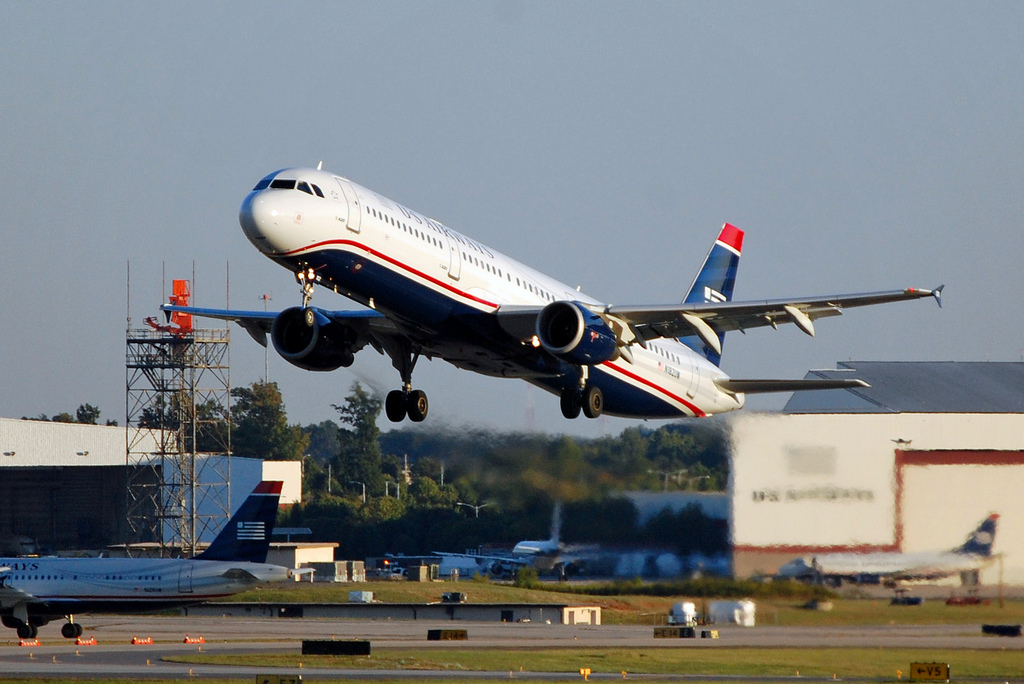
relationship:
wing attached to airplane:
[496, 284, 948, 365] [161, 159, 949, 423]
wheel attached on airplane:
[384, 390, 436, 423] [237, 167, 879, 453]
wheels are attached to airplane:
[557, 381, 605, 418] [161, 159, 949, 423]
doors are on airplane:
[332, 178, 367, 231] [161, 159, 949, 423]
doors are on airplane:
[438, 223, 471, 288] [161, 159, 949, 423]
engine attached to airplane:
[534, 297, 622, 368] [161, 159, 949, 423]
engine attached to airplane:
[269, 304, 360, 371] [161, 159, 949, 423]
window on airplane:
[267, 174, 300, 196] [161, 159, 949, 423]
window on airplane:
[297, 174, 311, 196] [161, 159, 949, 423]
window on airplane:
[306, 181, 330, 197] [161, 159, 949, 423]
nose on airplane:
[239, 155, 324, 259] [161, 159, 949, 423]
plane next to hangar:
[781, 507, 1000, 592] [727, 360, 1023, 585]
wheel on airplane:
[556, 373, 609, 419] [161, 159, 949, 423]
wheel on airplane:
[282, 263, 326, 346] [161, 159, 949, 423]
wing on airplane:
[161, 299, 388, 371] [161, 159, 949, 423]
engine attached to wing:
[269, 304, 360, 371] [161, 299, 388, 371]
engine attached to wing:
[530, 297, 623, 367] [496, 284, 948, 365]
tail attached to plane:
[195, 477, 282, 560] [1, 475, 298, 638]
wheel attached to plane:
[59, 608, 86, 643] [1, 475, 298, 638]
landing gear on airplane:
[379, 353, 609, 421] [161, 159, 948, 421]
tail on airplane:
[662, 220, 745, 359] [161, 159, 949, 423]